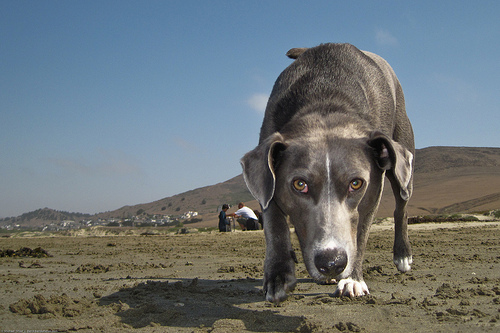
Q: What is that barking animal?
A: Dog.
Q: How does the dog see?
A: Eyes.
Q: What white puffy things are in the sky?
A: Clouds.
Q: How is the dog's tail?
A: Wagging.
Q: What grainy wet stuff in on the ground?
A: Sand.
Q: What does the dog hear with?
A: Ears.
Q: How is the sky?
A: Cloudy.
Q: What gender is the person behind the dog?
A: Male.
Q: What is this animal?
A: Dog.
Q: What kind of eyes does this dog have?
A: Brown.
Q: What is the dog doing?
A: Sniffing around.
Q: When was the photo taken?
A: Daytime.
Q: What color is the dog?
A: Charcoal black.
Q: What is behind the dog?
A: A hill.